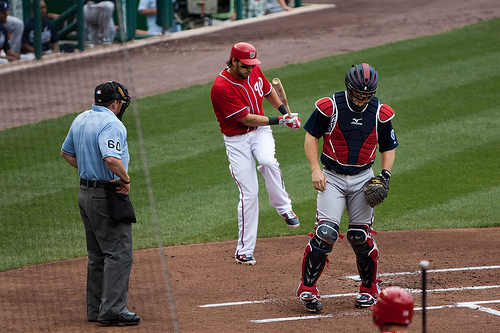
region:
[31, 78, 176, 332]
this is a person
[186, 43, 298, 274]
this is a person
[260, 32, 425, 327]
this is a person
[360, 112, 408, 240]
the hand of a person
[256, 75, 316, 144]
the hand of a person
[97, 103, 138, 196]
the hand of a person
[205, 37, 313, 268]
the player on one leg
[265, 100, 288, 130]
the black wirstbands on the player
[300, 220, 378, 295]
the pads on the mans legs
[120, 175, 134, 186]
the black band on the mans wrist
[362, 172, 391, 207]
the black cathers mit on the hand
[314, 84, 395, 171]
the chest protector on the mans chest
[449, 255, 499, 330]
the chalk lines on the dirt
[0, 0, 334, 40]
a bunch of people are watching the game.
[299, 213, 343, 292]
a umpire is wearing red and black leg pads.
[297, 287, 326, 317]
the umpire is wearing black and red sneakers.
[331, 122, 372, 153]
the umpire is wearing a red and black vest.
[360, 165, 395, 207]
the umpire is wearing a black and yellow glove.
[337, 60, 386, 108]
the umpire is wearing a black and red helmet.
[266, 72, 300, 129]
a player is holding a base ball bat.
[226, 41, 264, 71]
a player is wearing a red and white cap.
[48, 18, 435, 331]
the players are playing base ball.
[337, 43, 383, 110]
head of a person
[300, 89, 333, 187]
arm of a person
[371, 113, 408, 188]
arm of a person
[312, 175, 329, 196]
hand of a person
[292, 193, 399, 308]
legs of a person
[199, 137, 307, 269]
legs of a person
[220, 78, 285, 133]
arm of a person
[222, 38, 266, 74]
head of a person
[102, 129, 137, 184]
arm of a person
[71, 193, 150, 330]
legs of a person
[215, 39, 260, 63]
hat on the head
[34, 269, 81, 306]
the net in front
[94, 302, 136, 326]
shoes on the feet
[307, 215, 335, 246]
kneepads on the knees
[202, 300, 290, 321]
white lines in dirt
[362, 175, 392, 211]
glove on the hand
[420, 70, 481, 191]
striped pattern in grass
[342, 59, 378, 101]
helmet on the head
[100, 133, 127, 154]
number on the sleeve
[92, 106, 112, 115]
collar of the shirt